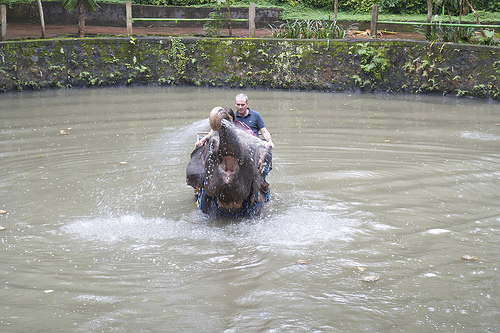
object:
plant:
[266, 14, 348, 51]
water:
[1, 219, 115, 332]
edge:
[3, 37, 498, 50]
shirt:
[222, 107, 266, 138]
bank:
[5, 35, 499, 102]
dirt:
[2, 40, 499, 98]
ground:
[392, 199, 414, 229]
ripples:
[340, 294, 379, 316]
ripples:
[422, 258, 444, 281]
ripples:
[211, 264, 271, 275]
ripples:
[471, 219, 498, 241]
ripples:
[68, 276, 133, 303]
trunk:
[208, 107, 240, 155]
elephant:
[185, 105, 271, 221]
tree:
[363, 0, 428, 13]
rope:
[133, 18, 249, 22]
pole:
[123, 0, 132, 36]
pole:
[249, 1, 256, 37]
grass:
[265, 20, 344, 40]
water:
[390, 110, 466, 179]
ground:
[379, 128, 442, 181]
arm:
[258, 120, 272, 142]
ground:
[365, 57, 410, 91]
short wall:
[0, 35, 500, 97]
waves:
[134, 189, 334, 281]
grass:
[280, 9, 498, 25]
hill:
[1, 28, 498, 99]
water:
[60, 92, 146, 134]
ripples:
[8, 113, 497, 199]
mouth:
[215, 152, 240, 177]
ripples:
[304, 282, 351, 304]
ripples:
[192, 243, 231, 273]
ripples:
[275, 241, 300, 266]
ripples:
[324, 217, 371, 245]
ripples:
[2, 277, 97, 302]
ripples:
[232, 294, 286, 323]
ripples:
[393, 206, 456, 246]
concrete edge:
[4, 24, 489, 94]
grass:
[111, 35, 228, 75]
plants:
[71, 41, 226, 79]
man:
[232, 93, 275, 152]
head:
[234, 94, 249, 113]